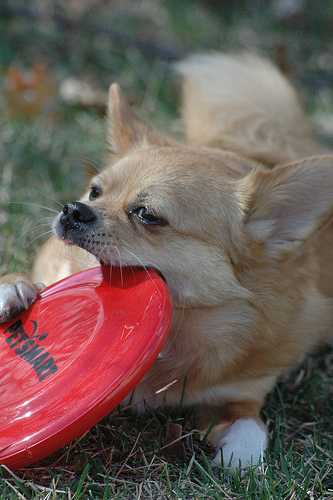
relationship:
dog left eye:
[30, 112, 332, 388] [132, 201, 167, 228]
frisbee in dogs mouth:
[5, 251, 181, 462] [55, 199, 181, 292]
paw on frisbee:
[4, 269, 46, 339] [6, 272, 162, 473]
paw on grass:
[212, 418, 269, 473] [214, 468, 308, 493]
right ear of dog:
[98, 92, 141, 138] [2, 73, 322, 395]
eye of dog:
[87, 182, 104, 202] [1, 48, 332, 481]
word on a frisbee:
[3, 318, 67, 390] [5, 251, 181, 462]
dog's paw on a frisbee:
[0, 268, 49, 332] [1, 259, 170, 466]